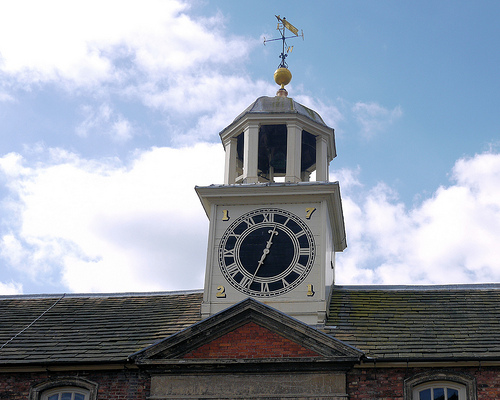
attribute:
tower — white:
[184, 31, 363, 371]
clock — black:
[228, 198, 385, 336]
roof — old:
[23, 262, 485, 381]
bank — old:
[22, 222, 462, 391]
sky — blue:
[64, 7, 495, 235]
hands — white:
[234, 227, 292, 267]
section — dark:
[17, 289, 114, 333]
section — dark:
[45, 303, 144, 373]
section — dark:
[447, 271, 481, 323]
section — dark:
[413, 283, 486, 383]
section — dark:
[376, 280, 456, 376]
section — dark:
[348, 275, 438, 376]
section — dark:
[94, 283, 177, 367]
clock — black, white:
[206, 191, 336, 321]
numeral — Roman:
[257, 202, 284, 231]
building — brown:
[3, 13, 499, 397]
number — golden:
[298, 275, 328, 305]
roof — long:
[4, 275, 499, 389]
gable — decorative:
[119, 291, 379, 384]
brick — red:
[170, 311, 314, 367]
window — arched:
[393, 359, 478, 398]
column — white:
[277, 119, 315, 187]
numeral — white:
[252, 202, 283, 232]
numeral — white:
[276, 209, 300, 233]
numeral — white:
[285, 220, 317, 245]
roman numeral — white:
[297, 244, 311, 255]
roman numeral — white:
[288, 260, 309, 278]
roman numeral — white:
[258, 277, 272, 294]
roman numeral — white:
[238, 270, 255, 293]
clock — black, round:
[214, 204, 320, 302]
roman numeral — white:
[223, 259, 244, 280]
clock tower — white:
[190, 10, 350, 332]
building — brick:
[3, 274, 495, 399]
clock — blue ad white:
[182, 182, 332, 307]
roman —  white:
[277, 276, 294, 290]